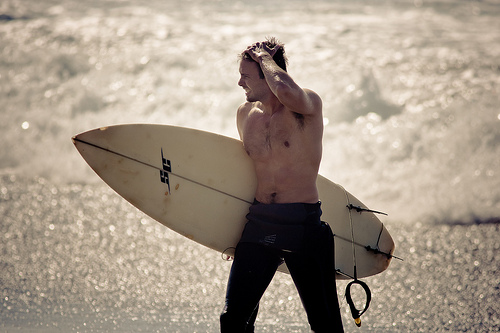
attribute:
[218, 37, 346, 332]
man — shirtless, bare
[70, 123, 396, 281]
surfboard — white, dirty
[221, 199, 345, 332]
wetsuit — black, wet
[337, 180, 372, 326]
rope — black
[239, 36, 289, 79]
hair — black